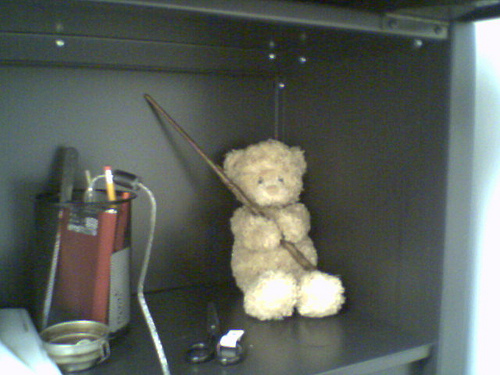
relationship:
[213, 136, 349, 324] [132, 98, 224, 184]
bear holding stick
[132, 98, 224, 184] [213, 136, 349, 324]
stick on bear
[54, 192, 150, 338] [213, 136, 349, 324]
glass near bear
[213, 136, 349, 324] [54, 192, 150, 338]
bear near glass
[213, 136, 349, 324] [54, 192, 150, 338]
bear next to glass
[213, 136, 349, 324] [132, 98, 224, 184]
bear near stick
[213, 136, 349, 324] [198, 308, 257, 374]
bear near scissors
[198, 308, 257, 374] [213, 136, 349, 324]
scissors near bear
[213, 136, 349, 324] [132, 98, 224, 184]
bear with stick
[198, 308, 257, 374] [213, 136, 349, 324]
scissors next to bear